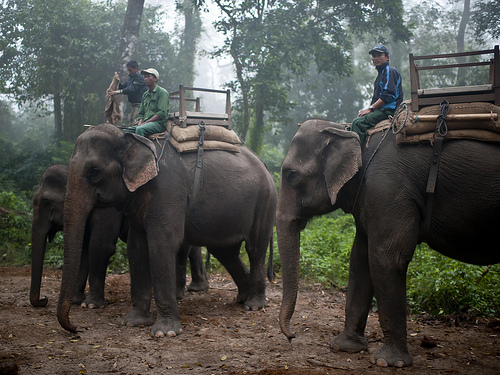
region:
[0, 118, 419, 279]
three elephants standing together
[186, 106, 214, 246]
strap that goes around the elephant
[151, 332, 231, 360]
toes of the elephant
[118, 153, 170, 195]
pink on the elephant's ear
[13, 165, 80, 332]
elephant is smaller than the other elephants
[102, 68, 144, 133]
man holding blanket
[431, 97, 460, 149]
rope on side of seat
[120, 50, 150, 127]
man standing on elephant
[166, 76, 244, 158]
seats on top of the elephant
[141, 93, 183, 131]
man wearing a green shirt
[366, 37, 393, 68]
the head of a man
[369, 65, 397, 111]
the arm of a man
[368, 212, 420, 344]
the leg of an elephant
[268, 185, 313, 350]
the trunk of an elephant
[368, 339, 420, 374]
the foot of an elephant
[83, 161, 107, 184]
the eye of an elephant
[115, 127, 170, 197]
the ear of an elephant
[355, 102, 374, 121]
the hand of a man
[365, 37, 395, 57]
a baseball cap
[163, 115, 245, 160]
brown sacks on the elephant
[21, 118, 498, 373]
Three elephants standing in jungle.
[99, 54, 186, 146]
Men riding on back of elephants.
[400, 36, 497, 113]
Hathi howdah on back of elephant.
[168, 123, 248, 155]
Pillows underneath hathi howdah on back of elephant.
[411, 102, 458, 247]
Strap holding hathi howdah on back of elephant.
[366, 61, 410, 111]
Man on elephant's back dressed in navy blue jacket with light blue accent.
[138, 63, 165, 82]
Man wearing tan baseball cap.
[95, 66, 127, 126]
Man holding rug in hands.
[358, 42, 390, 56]
Man wearing navy blue baseball cap.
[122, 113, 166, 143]
Elephant rider wearing green pants.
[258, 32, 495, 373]
a man sits in an elephant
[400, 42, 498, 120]
a bench in back of elephant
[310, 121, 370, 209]
ear of elephant is big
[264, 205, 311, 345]
trunk of elephant is long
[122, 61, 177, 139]
man wearing green cloths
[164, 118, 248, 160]
two brown pillows on a elephant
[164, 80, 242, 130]
a sit on top of pillows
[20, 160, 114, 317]
small elephant next to big elephant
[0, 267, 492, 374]
elephants stand on a soil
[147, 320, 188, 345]
three toenails of elephant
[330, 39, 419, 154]
The man is sitting on top of the elephant.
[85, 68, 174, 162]
Two men sitting on top of elephants.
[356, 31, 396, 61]
The man is wearing a cap.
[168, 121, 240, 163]
Pillows on top of the elephant.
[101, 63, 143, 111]
The man is standing on top of the elephant.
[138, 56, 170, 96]
The man is wearing a white cap.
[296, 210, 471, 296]
The grass is green.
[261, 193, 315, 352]
The trunk of the elephant is long.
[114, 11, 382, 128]
Woods in the background.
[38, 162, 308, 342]
The elephants is standing in the dirt.